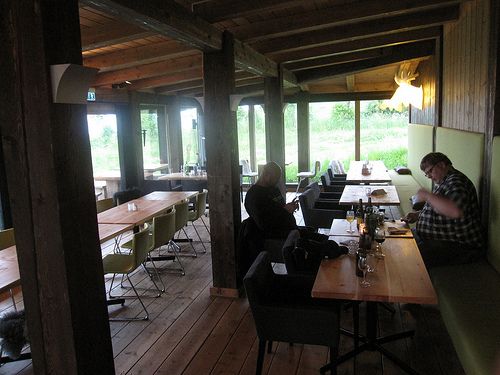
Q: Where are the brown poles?
A: Left of bar.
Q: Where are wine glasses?
A: Table to right.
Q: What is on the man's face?
A: Glasses.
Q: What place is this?
A: Restaurant.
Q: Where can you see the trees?
A: Outside of the window.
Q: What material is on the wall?
A: Wood.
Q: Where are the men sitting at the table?
A: Restaurant.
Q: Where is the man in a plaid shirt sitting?
A: Wall bench.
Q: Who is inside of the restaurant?
A: Two men.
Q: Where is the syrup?
A: Hand of the customer in plaid shirt.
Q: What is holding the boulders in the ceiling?
A: Wooden beams.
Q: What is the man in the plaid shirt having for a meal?
A: Pancakes.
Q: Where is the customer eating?
A: Wooden table.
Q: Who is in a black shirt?
A: A man.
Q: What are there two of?
A: Two men.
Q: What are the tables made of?
A: Wood.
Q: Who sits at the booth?
A: A man.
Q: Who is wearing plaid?
A: Man on right.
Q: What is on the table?
A: Glasses and beers.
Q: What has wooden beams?
A: The room.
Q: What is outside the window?
A: Grass.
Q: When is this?
A: Daytime.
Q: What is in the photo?
A: Tables.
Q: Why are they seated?
A: Relaxing.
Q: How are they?
A: Relaxed.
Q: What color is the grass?
A: Green.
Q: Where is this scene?
A: At a restaurant.